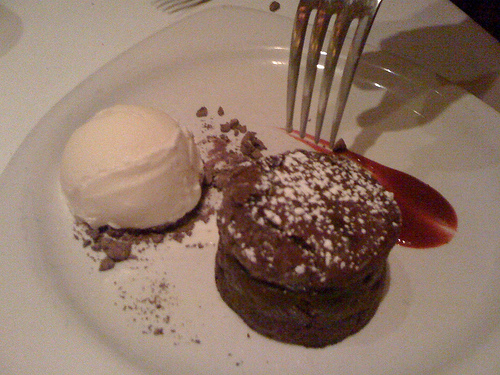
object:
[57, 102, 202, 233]
ice cream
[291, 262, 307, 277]
powder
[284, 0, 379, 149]
fork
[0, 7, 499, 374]
plate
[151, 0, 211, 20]
shadow fork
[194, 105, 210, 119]
crumbs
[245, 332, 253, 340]
crumbs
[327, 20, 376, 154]
prongs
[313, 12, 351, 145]
prongs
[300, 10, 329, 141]
prongs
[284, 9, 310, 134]
prongs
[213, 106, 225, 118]
powder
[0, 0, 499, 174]
table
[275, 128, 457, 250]
sauce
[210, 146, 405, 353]
brownie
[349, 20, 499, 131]
shadow